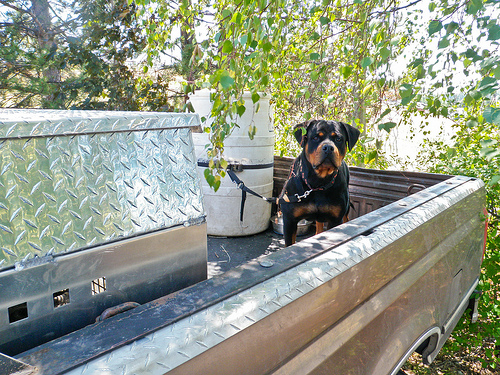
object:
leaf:
[250, 90, 262, 105]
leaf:
[428, 15, 443, 39]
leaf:
[260, 35, 275, 57]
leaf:
[361, 147, 380, 168]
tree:
[156, 3, 228, 109]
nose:
[312, 142, 342, 172]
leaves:
[223, 11, 232, 21]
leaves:
[237, 104, 245, 116]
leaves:
[207, 175, 215, 187]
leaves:
[212, 179, 222, 194]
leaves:
[186, 16, 475, 136]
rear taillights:
[479, 202, 488, 260]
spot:
[316, 132, 325, 140]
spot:
[327, 129, 338, 139]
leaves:
[184, 13, 277, 99]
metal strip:
[24, 175, 479, 369]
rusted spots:
[147, 289, 222, 311]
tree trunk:
[30, 1, 64, 112]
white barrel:
[192, 84, 270, 236]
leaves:
[133, 0, 376, 112]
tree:
[42, 1, 481, 215]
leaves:
[281, 35, 451, 150]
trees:
[43, 13, 493, 214]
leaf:
[464, 56, 474, 65]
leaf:
[361, 54, 371, 66]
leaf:
[481, 102, 498, 130]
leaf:
[378, 120, 398, 133]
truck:
[6, 78, 481, 373]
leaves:
[202, 164, 221, 193]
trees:
[14, 9, 83, 87]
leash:
[197, 158, 284, 204]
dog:
[258, 100, 390, 231]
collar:
[278, 175, 332, 205]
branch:
[141, 15, 462, 146]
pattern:
[24, 112, 196, 239]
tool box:
[1, 95, 233, 307]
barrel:
[170, 51, 282, 249]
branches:
[75, 3, 418, 103]